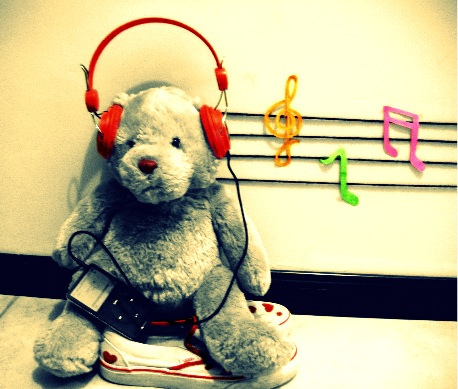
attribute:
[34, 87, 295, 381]
teddy bear — gray, listening to music, grey, soft, smooth, furry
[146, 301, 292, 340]
shoe — white, red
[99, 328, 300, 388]
shoe — white, red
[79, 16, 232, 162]
headphones — red, playing music, vibrant red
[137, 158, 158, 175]
nose — red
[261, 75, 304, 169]
music symbol — orange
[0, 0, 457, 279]
wall — black, tan, beige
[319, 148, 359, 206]
music note — green, pink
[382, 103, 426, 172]
music note — purple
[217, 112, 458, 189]
music symbol — black, lined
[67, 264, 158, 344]
ipod — black, grey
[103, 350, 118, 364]
heart — small, red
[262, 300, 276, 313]
heart — small, red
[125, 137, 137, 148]
eye — black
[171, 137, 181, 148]
eye — black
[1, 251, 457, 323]
border — black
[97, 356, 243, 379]
stripe — red